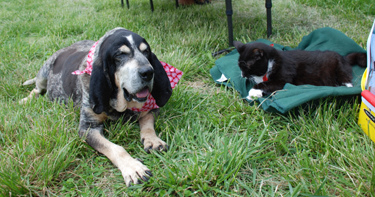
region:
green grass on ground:
[22, 145, 49, 170]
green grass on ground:
[45, 129, 65, 158]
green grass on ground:
[19, 87, 39, 108]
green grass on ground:
[56, 103, 75, 128]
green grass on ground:
[165, 167, 181, 182]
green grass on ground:
[184, 153, 221, 186]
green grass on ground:
[233, 129, 264, 168]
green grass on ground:
[288, 133, 321, 176]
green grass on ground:
[249, 123, 275, 140]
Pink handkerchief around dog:
[65, 25, 187, 114]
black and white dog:
[6, 23, 189, 185]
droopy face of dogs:
[85, 17, 171, 118]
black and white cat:
[221, 16, 371, 121]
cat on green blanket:
[229, 32, 360, 117]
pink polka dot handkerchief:
[63, 31, 183, 122]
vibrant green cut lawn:
[0, 0, 367, 192]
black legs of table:
[222, 0, 232, 45]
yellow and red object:
[350, 7, 373, 143]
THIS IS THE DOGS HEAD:
[96, 26, 159, 109]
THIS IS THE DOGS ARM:
[81, 108, 169, 186]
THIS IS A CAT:
[230, 36, 373, 101]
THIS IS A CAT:
[234, 39, 270, 80]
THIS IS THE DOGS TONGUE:
[133, 89, 152, 99]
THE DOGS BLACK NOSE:
[137, 66, 155, 80]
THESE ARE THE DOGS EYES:
[116, 44, 152, 56]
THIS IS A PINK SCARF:
[70, 37, 184, 113]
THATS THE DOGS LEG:
[12, 85, 43, 106]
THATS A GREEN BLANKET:
[207, 24, 368, 114]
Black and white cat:
[229, 30, 366, 101]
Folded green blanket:
[202, 49, 247, 95]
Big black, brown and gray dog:
[22, 24, 186, 184]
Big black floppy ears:
[89, 45, 175, 122]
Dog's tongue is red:
[130, 88, 153, 105]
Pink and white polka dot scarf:
[73, 23, 183, 116]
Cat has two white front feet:
[242, 86, 267, 99]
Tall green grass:
[168, 99, 258, 174]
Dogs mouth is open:
[117, 73, 160, 108]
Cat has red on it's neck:
[233, 36, 275, 84]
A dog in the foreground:
[15, 23, 177, 191]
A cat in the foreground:
[211, 17, 361, 107]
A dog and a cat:
[15, 15, 368, 191]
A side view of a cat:
[223, 30, 369, 105]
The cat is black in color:
[223, 28, 368, 108]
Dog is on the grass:
[13, 21, 186, 188]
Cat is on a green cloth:
[207, 14, 369, 129]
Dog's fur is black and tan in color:
[21, 23, 189, 188]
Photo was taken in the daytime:
[0, 1, 368, 190]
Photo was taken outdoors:
[2, 0, 370, 191]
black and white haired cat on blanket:
[232, 39, 365, 101]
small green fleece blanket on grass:
[210, 26, 367, 114]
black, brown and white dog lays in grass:
[18, 26, 172, 185]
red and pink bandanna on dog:
[70, 39, 184, 111]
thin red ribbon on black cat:
[261, 41, 275, 81]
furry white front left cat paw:
[248, 87, 261, 95]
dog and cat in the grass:
[14, 19, 371, 189]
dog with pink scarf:
[11, 29, 204, 187]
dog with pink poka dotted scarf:
[13, 14, 194, 188]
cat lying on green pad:
[228, 28, 366, 113]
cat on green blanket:
[217, 24, 367, 111]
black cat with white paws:
[225, 29, 371, 121]